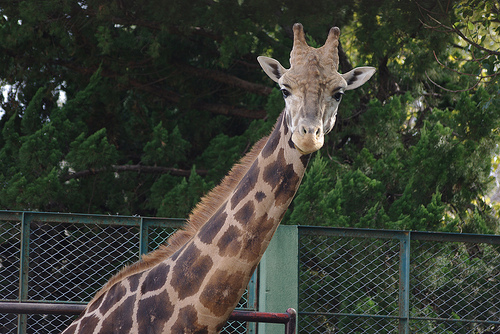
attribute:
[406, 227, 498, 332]
wire-meshed fance — blue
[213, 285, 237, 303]
dot — white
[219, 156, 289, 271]
giraffe's neck — long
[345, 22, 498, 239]
tree — big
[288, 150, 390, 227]
branch — leafy, green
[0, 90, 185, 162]
tree branch — green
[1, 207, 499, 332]
fence — mesh, wire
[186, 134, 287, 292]
neck — tall , brown 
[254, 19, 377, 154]
head — brown, small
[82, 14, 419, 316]
giraffe — brown, tall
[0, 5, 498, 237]
tree — green, leafy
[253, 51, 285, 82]
ears — black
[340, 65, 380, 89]
ears — black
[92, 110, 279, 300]
hair — brown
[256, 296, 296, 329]
railing — red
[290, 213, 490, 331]
chain — green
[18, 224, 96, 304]
chain — green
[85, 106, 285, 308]
mane — brown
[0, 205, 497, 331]
mesh fence — blue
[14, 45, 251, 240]
tree — green, leafy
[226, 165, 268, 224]
spot — light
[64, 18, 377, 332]
girrafe — brown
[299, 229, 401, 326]
mesh fence — wire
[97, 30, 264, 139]
tree branch — big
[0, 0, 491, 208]
tree — leafy, green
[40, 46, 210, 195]
tree branch — big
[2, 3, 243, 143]
tree branch — green 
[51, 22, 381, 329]
giraffe — tall, brown